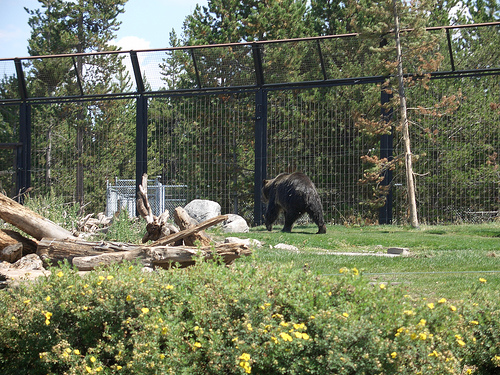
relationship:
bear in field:
[260, 172, 328, 235] [275, 230, 485, 359]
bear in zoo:
[244, 147, 325, 227] [61, 33, 466, 334]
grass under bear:
[2, 219, 498, 374] [261, 170, 326, 232]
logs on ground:
[76, 248, 207, 260] [255, 235, 497, 267]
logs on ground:
[0, 202, 57, 236] [255, 235, 497, 267]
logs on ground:
[162, 215, 232, 235] [255, 235, 497, 267]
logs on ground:
[54, 240, 91, 256] [255, 235, 497, 267]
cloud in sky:
[79, 31, 176, 98] [3, 1, 206, 99]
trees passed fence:
[3, 1, 499, 227] [0, 20, 499, 225]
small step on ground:
[384, 242, 419, 257] [359, 254, 464, 286]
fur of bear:
[282, 174, 307, 199] [238, 179, 423, 293]